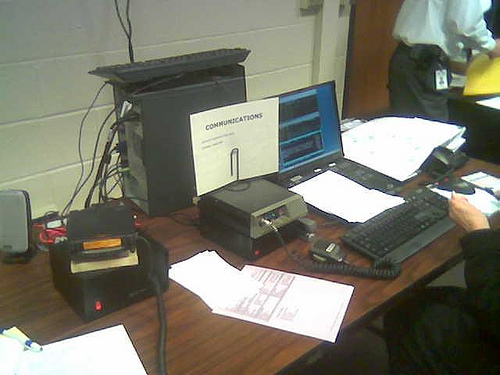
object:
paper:
[209, 263, 356, 344]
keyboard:
[340, 187, 457, 266]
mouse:
[432, 179, 476, 196]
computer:
[259, 78, 429, 225]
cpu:
[110, 63, 249, 219]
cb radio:
[197, 177, 312, 239]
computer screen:
[262, 80, 344, 176]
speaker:
[0, 188, 37, 265]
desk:
[0, 152, 500, 373]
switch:
[94, 300, 104, 311]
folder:
[461, 53, 500, 98]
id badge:
[435, 68, 450, 91]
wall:
[1, 0, 355, 224]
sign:
[187, 95, 282, 199]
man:
[383, 189, 500, 372]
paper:
[287, 168, 406, 224]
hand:
[448, 189, 493, 232]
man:
[387, 0, 500, 123]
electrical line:
[60, 106, 124, 216]